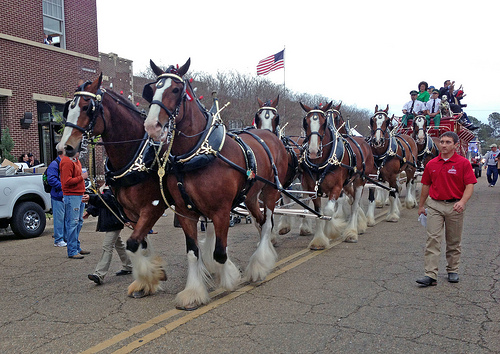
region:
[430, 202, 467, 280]
the pants aregrey in color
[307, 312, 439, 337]
the floor is grey in color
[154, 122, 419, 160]
the horses are same in color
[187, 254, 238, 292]
the horses legs are white in color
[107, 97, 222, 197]
the horses are brown in color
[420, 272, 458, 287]
the shoes are black in color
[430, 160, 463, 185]
shitrt is red in color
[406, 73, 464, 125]
peoiple caried by the horses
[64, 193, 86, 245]
the pants are blue faded in color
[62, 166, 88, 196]
the sweater is red in color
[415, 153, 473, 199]
the shirt is red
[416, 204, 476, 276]
the pants are brown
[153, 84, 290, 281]
the horses are brown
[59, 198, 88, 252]
the jeans are blue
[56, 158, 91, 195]
the shirtis red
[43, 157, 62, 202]
the shirt is blue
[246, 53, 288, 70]
the flag is american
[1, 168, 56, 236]
the truck is white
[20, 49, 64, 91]
the wall is made of bricks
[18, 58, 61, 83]
the bricks are brown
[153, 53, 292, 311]
this is a horse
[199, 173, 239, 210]
the horse is brown in color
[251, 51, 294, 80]
this is a flag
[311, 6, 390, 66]
this is the sky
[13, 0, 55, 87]
this is a building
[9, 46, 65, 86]
this is the wall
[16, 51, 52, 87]
the wall is brown in color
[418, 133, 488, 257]
this is a man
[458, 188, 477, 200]
the man is light skinned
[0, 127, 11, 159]
this is a tree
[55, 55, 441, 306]
several large horses in street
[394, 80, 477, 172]
horse drawn carriage with people on top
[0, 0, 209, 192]
large brick building behind horses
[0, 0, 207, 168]
the bricks are red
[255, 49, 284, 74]
American flag on pole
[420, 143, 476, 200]
man is wearing red polo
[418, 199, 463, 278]
man is wearing khakis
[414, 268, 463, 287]
person has on black athletic shoes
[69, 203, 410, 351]
double yellow line in street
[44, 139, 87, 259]
group of people beside horses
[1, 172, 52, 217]
bed of a white truck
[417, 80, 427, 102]
woman in buggy wearing a green shirt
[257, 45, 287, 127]
American flag on a silver pole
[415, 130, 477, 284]
man in red polo and khakis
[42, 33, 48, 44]
person in an open window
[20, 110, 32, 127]
black object on the brick building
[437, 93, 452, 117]
skeleton thing silling in the carriage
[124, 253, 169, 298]
tiny yellow puppy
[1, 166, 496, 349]
part of a cracked street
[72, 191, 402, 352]
hopefully that will help to alleviate some of Billy's pain